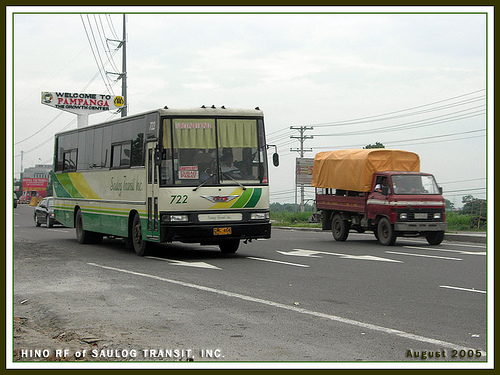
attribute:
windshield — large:
[162, 117, 266, 186]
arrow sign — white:
[148, 253, 221, 276]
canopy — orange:
[308, 148, 423, 194]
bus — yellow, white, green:
[48, 111, 272, 259]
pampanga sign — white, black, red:
[41, 92, 125, 119]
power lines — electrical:
[312, 106, 500, 142]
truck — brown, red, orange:
[306, 147, 451, 246]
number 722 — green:
[168, 191, 190, 208]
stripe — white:
[371, 198, 446, 207]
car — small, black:
[27, 198, 60, 228]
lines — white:
[117, 279, 326, 306]